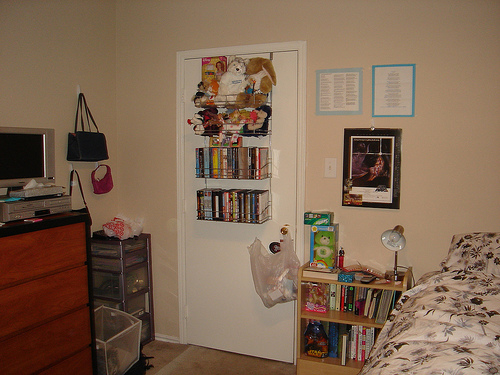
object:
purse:
[67, 92, 111, 163]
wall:
[1, 0, 118, 237]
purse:
[91, 164, 114, 195]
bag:
[248, 224, 302, 308]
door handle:
[280, 224, 288, 235]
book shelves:
[195, 187, 272, 223]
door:
[170, 41, 308, 365]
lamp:
[381, 224, 407, 281]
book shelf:
[296, 259, 414, 373]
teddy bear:
[310, 227, 337, 267]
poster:
[343, 127, 404, 210]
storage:
[89, 232, 156, 346]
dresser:
[0, 210, 97, 374]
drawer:
[0, 219, 88, 288]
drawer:
[0, 262, 90, 338]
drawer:
[0, 304, 93, 374]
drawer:
[36, 348, 94, 373]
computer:
[0, 126, 57, 193]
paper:
[316, 66, 364, 117]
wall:
[115, 1, 498, 365]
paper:
[371, 63, 416, 118]